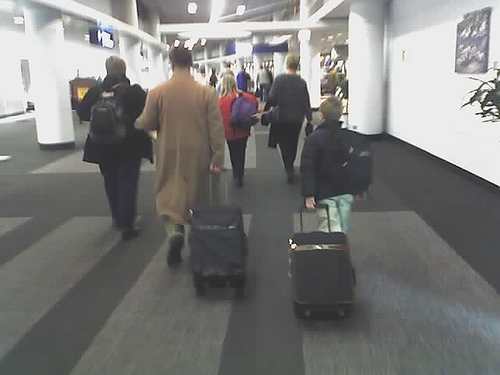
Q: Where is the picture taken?
A: An airport.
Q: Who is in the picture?
A: Men and women.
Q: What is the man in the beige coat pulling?
A: Luggage.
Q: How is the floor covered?
A: Carpeted.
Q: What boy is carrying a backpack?
A: The boy also pulling luggage.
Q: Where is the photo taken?
A: An airport.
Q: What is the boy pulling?
A: A suitcase.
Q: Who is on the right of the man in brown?
A: The little boy.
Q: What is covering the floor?
A: Carpet.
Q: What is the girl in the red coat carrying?
A: A purple backpack.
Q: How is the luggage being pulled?
A: On wheels.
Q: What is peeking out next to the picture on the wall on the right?
A: A plant.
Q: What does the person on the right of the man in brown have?
A: A backpack.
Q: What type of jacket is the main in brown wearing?
A: A trench coat.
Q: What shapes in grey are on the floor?
A: Rectangles.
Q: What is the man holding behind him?
A: Luggage.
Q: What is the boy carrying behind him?
A: Luggage.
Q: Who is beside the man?
A: The boy.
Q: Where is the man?
A: At the airport.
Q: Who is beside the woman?
A: The man.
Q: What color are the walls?
A: White.